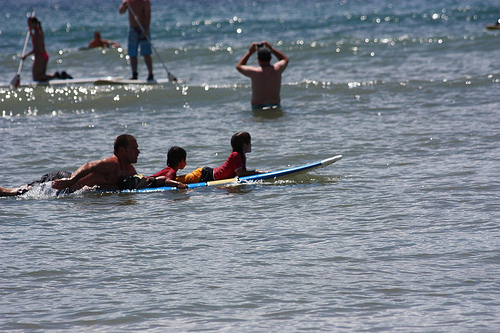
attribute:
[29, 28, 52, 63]
bikini — pink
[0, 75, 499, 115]
wave — white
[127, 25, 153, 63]
swim trunks — blue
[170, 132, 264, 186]
kid — laying down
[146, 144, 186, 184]
kid — laying down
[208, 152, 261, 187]
shirt — red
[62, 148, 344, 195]
surfboard — blue and white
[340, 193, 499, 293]
water — blue